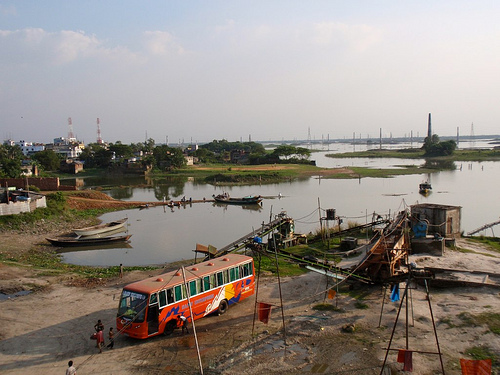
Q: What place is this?
A: It is a shore.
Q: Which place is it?
A: It is a shore.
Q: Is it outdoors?
A: Yes, it is outdoors.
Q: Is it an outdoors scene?
A: Yes, it is outdoors.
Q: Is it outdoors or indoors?
A: It is outdoors.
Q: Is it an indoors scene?
A: No, it is outdoors.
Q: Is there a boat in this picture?
A: Yes, there is a boat.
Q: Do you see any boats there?
A: Yes, there is a boat.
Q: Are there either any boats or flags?
A: Yes, there is a boat.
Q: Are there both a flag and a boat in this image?
A: Yes, there are both a boat and a flag.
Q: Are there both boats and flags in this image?
A: Yes, there are both a boat and a flag.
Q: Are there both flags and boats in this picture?
A: Yes, there are both a boat and a flag.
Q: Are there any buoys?
A: No, there are no buoys.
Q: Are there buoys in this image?
A: No, there are no buoys.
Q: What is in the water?
A: The boat is in the water.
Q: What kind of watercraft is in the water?
A: The watercraft is a boat.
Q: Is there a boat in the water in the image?
A: Yes, there is a boat in the water.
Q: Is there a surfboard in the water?
A: No, there is a boat in the water.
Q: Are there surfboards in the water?
A: No, there is a boat in the water.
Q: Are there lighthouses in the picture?
A: No, there are no lighthouses.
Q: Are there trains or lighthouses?
A: No, there are no lighthouses or trains.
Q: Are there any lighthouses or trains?
A: No, there are no lighthouses or trains.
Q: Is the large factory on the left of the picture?
A: Yes, the factory is on the left of the image.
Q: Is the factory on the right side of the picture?
A: No, the factory is on the left of the image.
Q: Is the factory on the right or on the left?
A: The factory is on the left of the image.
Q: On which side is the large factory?
A: The factory is on the left of the image.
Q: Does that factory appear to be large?
A: Yes, the factory is large.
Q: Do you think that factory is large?
A: Yes, the factory is large.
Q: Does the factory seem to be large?
A: Yes, the factory is large.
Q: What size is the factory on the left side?
A: The factory is large.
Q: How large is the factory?
A: The factory is large.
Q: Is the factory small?
A: No, the factory is large.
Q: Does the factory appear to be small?
A: No, the factory is large.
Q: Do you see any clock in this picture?
A: No, there are no clocks.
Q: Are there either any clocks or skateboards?
A: No, there are no clocks or skateboards.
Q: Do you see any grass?
A: Yes, there is grass.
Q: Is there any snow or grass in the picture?
A: Yes, there is grass.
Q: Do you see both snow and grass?
A: No, there is grass but no snow.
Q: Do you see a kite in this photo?
A: No, there are no kites.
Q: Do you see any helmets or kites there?
A: No, there are no kites or helmets.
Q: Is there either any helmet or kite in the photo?
A: No, there are no kites or helmets.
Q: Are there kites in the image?
A: No, there are no kites.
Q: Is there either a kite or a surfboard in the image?
A: No, there are no kites or surfboards.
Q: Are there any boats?
A: Yes, there is a boat.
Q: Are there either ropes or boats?
A: Yes, there is a boat.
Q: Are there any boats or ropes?
A: Yes, there is a boat.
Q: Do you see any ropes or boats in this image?
A: Yes, there is a boat.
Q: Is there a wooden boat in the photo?
A: Yes, there is a wood boat.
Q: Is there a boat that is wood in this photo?
A: Yes, there is a wood boat.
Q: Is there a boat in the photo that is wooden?
A: Yes, there is a boat that is wooden.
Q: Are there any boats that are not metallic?
A: Yes, there is a wooden boat.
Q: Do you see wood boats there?
A: Yes, there is a boat that is made of wood.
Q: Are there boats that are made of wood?
A: Yes, there is a boat that is made of wood.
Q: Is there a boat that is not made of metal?
A: Yes, there is a boat that is made of wood.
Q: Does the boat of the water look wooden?
A: Yes, the boat is wooden.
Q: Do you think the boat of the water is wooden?
A: Yes, the boat is wooden.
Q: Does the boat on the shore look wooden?
A: Yes, the boat is wooden.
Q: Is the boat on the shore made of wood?
A: Yes, the boat is made of wood.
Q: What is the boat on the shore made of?
A: The boat is made of wood.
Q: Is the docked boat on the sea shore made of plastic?
A: No, the boat is made of wood.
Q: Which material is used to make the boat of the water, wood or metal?
A: The boat is made of wood.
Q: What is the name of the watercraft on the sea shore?
A: The watercraft is a boat.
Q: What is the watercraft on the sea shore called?
A: The watercraft is a boat.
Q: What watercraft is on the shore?
A: The watercraft is a boat.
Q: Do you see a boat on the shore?
A: Yes, there is a boat on the shore.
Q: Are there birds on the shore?
A: No, there is a boat on the shore.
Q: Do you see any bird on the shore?
A: No, there is a boat on the shore.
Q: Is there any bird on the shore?
A: No, there is a boat on the shore.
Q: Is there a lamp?
A: No, there are no lamps.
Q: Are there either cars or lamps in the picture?
A: No, there are no lamps or cars.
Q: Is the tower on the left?
A: Yes, the tower is on the left of the image.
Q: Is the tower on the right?
A: No, the tower is on the left of the image.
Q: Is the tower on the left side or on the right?
A: The tower is on the left of the image.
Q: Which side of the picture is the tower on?
A: The tower is on the left of the image.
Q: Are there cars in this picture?
A: No, there are no cars.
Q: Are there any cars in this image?
A: No, there are no cars.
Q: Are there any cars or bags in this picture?
A: No, there are no cars or bags.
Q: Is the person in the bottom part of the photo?
A: Yes, the person is in the bottom of the image.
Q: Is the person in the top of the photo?
A: No, the person is in the bottom of the image.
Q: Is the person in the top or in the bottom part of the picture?
A: The person is in the bottom of the image.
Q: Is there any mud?
A: Yes, there is mud.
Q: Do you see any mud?
A: Yes, there is mud.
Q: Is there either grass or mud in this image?
A: Yes, there is mud.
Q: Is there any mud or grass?
A: Yes, there is mud.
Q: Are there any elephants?
A: No, there are no elephants.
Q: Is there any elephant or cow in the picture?
A: No, there are no elephants or cows.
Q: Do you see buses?
A: Yes, there is a bus.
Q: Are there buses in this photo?
A: Yes, there is a bus.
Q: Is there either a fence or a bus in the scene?
A: Yes, there is a bus.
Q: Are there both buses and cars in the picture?
A: No, there is a bus but no cars.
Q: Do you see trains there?
A: No, there are no trains.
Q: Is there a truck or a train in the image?
A: No, there are no trains or trucks.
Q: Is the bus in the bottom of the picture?
A: Yes, the bus is in the bottom of the image.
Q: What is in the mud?
A: The bus is in the mud.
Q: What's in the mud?
A: The bus is in the mud.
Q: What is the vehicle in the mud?
A: The vehicle is a bus.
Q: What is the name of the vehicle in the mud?
A: The vehicle is a bus.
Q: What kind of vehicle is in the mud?
A: The vehicle is a bus.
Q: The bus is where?
A: The bus is in the mud.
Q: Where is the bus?
A: The bus is in the mud.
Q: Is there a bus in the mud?
A: Yes, there is a bus in the mud.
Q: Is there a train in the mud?
A: No, there is a bus in the mud.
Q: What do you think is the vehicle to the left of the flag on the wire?
A: The vehicle is a bus.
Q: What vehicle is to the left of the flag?
A: The vehicle is a bus.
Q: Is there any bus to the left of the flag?
A: Yes, there is a bus to the left of the flag.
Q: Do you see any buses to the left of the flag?
A: Yes, there is a bus to the left of the flag.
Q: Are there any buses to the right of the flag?
A: No, the bus is to the left of the flag.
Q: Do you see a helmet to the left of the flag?
A: No, there is a bus to the left of the flag.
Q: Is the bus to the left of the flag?
A: Yes, the bus is to the left of the flag.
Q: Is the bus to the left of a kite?
A: No, the bus is to the left of the flag.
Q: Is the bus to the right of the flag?
A: No, the bus is to the left of the flag.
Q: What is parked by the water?
A: The bus is parked by the water.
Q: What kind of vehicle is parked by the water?
A: The vehicle is a bus.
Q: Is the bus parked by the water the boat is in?
A: Yes, the bus is parked by the water.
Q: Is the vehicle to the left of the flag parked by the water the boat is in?
A: Yes, the bus is parked by the water.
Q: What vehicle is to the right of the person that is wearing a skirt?
A: The vehicle is a bus.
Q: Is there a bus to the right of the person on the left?
A: Yes, there is a bus to the right of the person.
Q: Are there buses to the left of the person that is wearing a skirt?
A: No, the bus is to the right of the person.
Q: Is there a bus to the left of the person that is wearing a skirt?
A: No, the bus is to the right of the person.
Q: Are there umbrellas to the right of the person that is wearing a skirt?
A: No, there is a bus to the right of the person.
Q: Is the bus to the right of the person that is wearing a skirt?
A: Yes, the bus is to the right of the person.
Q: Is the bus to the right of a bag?
A: No, the bus is to the right of the person.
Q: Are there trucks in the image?
A: No, there are no trucks.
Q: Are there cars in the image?
A: No, there are no cars.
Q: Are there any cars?
A: No, there are no cars.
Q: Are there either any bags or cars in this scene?
A: No, there are no cars or bags.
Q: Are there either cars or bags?
A: No, there are no cars or bags.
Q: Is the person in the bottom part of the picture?
A: Yes, the person is in the bottom of the image.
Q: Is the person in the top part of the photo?
A: No, the person is in the bottom of the image.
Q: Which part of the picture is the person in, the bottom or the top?
A: The person is in the bottom of the image.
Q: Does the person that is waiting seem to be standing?
A: Yes, the person is standing.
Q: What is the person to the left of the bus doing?
A: The person is standing.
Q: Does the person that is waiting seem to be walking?
A: No, the person is standing.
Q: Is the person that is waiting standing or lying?
A: The person is standing.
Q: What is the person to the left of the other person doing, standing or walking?
A: The person is standing.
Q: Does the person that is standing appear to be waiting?
A: Yes, the person is waiting.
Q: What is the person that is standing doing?
A: The person is waiting.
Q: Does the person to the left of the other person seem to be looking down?
A: No, the person is waiting.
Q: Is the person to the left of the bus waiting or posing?
A: The person is waiting.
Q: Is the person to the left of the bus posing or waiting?
A: The person is waiting.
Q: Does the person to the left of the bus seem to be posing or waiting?
A: The person is waiting.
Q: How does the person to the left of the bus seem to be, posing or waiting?
A: The person is waiting.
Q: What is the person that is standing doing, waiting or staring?
A: The person is waiting.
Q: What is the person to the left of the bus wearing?
A: The person is wearing a skirt.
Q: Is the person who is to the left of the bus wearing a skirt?
A: Yes, the person is wearing a skirt.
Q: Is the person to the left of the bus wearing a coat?
A: No, the person is wearing a skirt.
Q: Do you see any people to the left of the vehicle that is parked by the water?
A: Yes, there is a person to the left of the bus.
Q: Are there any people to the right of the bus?
A: No, the person is to the left of the bus.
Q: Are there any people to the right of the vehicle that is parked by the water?
A: No, the person is to the left of the bus.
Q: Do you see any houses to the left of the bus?
A: No, there is a person to the left of the bus.